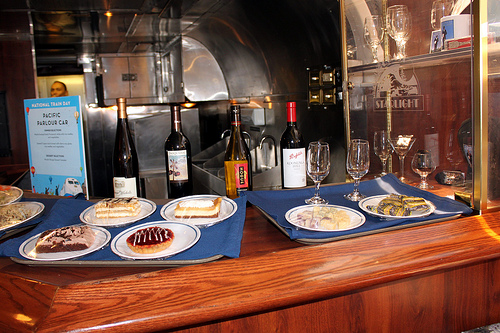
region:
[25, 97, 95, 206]
the menu is blue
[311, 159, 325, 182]
liquid in the glass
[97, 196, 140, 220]
the cake is on plate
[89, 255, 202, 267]
the tray is silver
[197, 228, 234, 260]
the cloth is blue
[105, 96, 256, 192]
wine in the bottles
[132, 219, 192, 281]
brown dessert with icing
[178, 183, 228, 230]
white dessert with icing on plate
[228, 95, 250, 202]
clear bottle in middle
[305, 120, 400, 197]
clear wine glasses on right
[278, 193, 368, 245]
plate of food on right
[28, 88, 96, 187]
blue printed sign on left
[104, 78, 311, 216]
line of wine bottles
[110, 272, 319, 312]
shiny wooden counter top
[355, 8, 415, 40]
empty glasses in case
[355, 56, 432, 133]
etched logo on glass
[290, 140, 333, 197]
glass on a tray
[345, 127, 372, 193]
glass on a tray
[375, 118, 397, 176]
glass on a tray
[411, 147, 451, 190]
glass on a bar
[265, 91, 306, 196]
wine bottle on bar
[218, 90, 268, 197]
wine botttle on bar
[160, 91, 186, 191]
wine bottle on bar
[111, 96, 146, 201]
wine bottle on bar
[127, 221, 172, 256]
pastry on a plate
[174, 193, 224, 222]
pastry on a plate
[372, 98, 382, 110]
white letter on glass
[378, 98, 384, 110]
white letter on glass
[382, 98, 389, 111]
white letter on glass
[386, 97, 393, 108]
white letter on glass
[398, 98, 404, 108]
white letter on glass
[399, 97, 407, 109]
white letter on glass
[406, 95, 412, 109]
white letter on glass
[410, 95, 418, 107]
white letter on glass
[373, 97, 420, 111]
white letters on glass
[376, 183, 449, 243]
a plate of food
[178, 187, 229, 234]
a plate of food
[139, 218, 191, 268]
a plate of food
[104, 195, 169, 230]
a plate of food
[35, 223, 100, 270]
a plate of food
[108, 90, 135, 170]
a bottle of wine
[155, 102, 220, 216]
a bottle of wine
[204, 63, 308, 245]
a bottle of wine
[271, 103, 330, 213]
a bottle of wine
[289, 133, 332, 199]
a glass on the table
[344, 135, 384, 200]
a glass on the table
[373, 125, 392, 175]
a glass on the table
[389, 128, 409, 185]
a glass on the table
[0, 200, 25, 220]
food on white plate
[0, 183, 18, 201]
food on white plate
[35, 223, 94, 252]
food on white plate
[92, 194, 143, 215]
food on white plate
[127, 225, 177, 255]
food on white plate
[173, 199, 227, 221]
food on white plate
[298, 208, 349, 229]
food on white plate